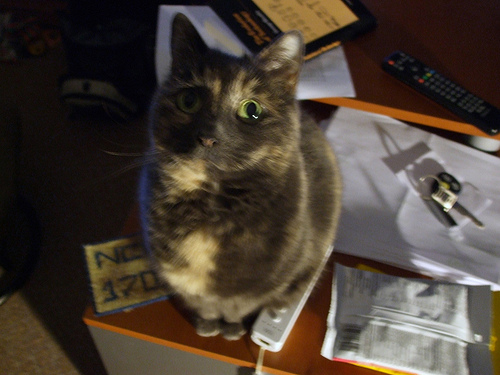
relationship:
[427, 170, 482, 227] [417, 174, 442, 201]
keys in key chain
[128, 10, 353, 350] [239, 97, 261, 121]
cat has eye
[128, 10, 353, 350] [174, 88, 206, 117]
cat has eye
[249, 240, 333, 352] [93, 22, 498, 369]
controller on desk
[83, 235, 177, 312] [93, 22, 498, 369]
sign on desk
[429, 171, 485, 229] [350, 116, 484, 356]
keys on desk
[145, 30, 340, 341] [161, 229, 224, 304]
cat has white chest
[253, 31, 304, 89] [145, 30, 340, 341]
ear of cat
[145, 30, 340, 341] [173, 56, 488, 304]
cat on desk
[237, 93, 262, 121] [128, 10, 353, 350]
eye of cat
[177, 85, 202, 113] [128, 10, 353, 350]
eye of cat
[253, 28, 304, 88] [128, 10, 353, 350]
ear of cat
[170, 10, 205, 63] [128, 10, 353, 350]
ear of cat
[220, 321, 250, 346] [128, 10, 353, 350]
paw of cat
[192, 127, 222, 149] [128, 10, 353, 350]
nose of cat